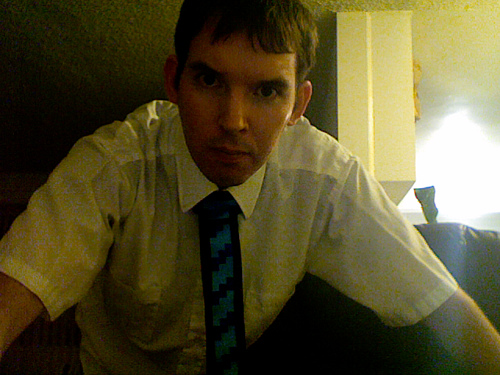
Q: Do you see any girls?
A: No, there are no girls.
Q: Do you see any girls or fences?
A: No, there are no girls or fences.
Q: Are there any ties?
A: Yes, there is a tie.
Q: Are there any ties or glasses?
A: Yes, there is a tie.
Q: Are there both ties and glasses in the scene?
A: No, there is a tie but no glasses.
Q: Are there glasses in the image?
A: No, there are no glasses.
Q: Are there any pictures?
A: No, there are no pictures.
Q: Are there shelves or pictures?
A: No, there are no pictures or shelves.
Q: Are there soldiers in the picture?
A: No, there are no soldiers.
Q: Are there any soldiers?
A: No, there are no soldiers.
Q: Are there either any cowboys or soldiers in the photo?
A: No, there are no soldiers or cowboys.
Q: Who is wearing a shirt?
A: The man is wearing a shirt.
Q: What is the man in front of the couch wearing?
A: The man is wearing a shirt.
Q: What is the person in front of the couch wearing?
A: The man is wearing a shirt.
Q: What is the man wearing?
A: The man is wearing a shirt.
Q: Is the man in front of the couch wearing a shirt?
A: Yes, the man is wearing a shirt.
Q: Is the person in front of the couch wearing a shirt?
A: Yes, the man is wearing a shirt.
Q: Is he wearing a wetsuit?
A: No, the man is wearing a shirt.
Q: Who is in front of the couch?
A: The man is in front of the couch.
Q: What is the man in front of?
A: The man is in front of the couch.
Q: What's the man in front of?
A: The man is in front of the couch.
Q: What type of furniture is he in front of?
A: The man is in front of the couch.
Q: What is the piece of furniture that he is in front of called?
A: The piece of furniture is a couch.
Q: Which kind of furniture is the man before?
A: The man is in front of the couch.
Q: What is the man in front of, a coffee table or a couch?
A: The man is in front of a couch.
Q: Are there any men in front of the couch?
A: Yes, there is a man in front of the couch.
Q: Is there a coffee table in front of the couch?
A: No, there is a man in front of the couch.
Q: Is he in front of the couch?
A: Yes, the man is in front of the couch.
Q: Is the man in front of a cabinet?
A: No, the man is in front of the couch.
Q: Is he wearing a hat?
A: No, the man is wearing a shirt.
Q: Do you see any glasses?
A: No, there are no glasses.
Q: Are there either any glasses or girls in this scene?
A: No, there are no glasses or girls.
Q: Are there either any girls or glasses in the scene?
A: No, there are no glasses or girls.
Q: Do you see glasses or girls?
A: No, there are no glasses or girls.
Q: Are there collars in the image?
A: Yes, there is a collar.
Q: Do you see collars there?
A: Yes, there is a collar.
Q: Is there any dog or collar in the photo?
A: Yes, there is a collar.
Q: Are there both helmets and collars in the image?
A: No, there is a collar but no helmets.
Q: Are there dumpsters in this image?
A: No, there are no dumpsters.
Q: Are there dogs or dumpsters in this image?
A: No, there are no dumpsters or dogs.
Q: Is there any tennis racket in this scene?
A: No, there are no rackets.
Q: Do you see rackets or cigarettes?
A: No, there are no rackets or cigarettes.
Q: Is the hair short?
A: Yes, the hair is short.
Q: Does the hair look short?
A: Yes, the hair is short.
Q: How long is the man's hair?
A: The hair is short.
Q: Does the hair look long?
A: No, the hair is short.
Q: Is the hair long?
A: No, the hair is short.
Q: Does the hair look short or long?
A: The hair is short.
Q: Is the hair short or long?
A: The hair is short.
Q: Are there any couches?
A: Yes, there is a couch.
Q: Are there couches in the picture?
A: Yes, there is a couch.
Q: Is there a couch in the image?
A: Yes, there is a couch.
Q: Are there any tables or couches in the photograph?
A: Yes, there is a couch.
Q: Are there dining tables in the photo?
A: No, there are no dining tables.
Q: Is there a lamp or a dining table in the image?
A: No, there are no dining tables or lamps.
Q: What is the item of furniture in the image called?
A: The piece of furniture is a couch.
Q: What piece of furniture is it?
A: The piece of furniture is a couch.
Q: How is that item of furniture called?
A: This is a couch.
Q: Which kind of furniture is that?
A: This is a couch.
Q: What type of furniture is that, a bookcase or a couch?
A: This is a couch.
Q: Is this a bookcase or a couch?
A: This is a couch.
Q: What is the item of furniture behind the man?
A: The piece of furniture is a couch.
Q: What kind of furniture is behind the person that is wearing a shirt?
A: The piece of furniture is a couch.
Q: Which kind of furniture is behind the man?
A: The piece of furniture is a couch.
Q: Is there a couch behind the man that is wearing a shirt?
A: Yes, there is a couch behind the man.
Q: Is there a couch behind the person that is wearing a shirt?
A: Yes, there is a couch behind the man.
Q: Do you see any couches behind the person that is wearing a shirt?
A: Yes, there is a couch behind the man.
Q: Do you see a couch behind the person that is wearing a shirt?
A: Yes, there is a couch behind the man.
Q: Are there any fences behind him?
A: No, there is a couch behind the man.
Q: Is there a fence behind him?
A: No, there is a couch behind the man.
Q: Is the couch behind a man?
A: Yes, the couch is behind a man.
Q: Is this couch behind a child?
A: No, the couch is behind a man.